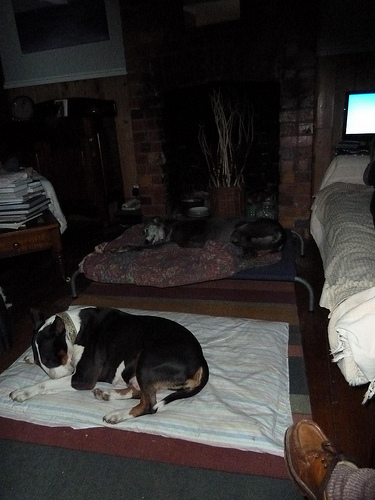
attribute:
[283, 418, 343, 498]
shoe — light brown, leather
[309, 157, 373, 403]
bed — part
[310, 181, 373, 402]
bedding — white and grey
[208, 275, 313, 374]
rug — striped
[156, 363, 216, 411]
tail — dog's, black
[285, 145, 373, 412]
couch — white covered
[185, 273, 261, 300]
table — brown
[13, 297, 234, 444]
dog — large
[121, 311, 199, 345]
back — black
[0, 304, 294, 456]
bed — dog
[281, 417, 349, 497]
shoe — man's, dirty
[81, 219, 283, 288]
dog bed — floral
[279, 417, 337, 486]
shoe — leather, brown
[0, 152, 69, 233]
books — pile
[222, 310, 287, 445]
blanket — white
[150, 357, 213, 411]
dog's tail — white, tip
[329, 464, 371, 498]
sock — grey striped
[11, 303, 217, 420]
dog — white, black, and brown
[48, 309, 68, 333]
ear — black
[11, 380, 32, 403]
paw — white, dog's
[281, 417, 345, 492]
shoe — brown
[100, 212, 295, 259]
dog — big, black , very large, white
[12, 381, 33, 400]
paw — white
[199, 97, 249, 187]
tree branches — decoration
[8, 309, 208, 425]
dog — black and white